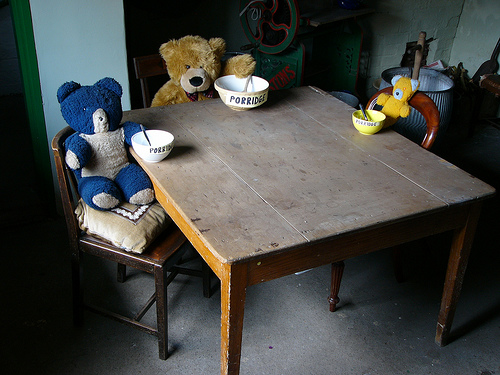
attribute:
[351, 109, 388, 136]
bowl — yellow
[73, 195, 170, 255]
throw pillow — light brown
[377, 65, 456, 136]
garbage can — metal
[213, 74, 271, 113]
bowl — tan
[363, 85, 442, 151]
chair — wooden, shiny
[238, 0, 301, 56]
wheel — green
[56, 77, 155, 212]
bear — stuffed, toy, white, blue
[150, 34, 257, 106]
teddy bear — light brown, brown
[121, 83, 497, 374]
dining table — wooden, weathered, old, wood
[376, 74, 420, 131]
teddy bear — sitting, small, yellow, white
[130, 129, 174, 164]
bowl — white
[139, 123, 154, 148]
eating utensil — gray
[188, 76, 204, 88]
nose — black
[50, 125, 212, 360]
chair — brown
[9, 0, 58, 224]
door frame — green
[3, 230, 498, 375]
flooring — bare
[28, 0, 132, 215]
wall — light blue